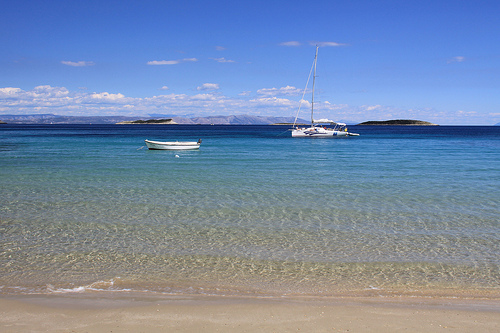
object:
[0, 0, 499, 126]
sky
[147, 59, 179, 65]
cloud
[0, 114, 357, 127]
horizon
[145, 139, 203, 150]
boat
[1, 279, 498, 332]
beach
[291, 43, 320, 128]
line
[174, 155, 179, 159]
disturbance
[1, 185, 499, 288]
riddles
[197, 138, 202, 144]
engine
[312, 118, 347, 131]
canopy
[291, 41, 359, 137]
base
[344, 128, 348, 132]
person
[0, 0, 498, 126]
background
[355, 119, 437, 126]
island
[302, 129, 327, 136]
design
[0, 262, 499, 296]
water